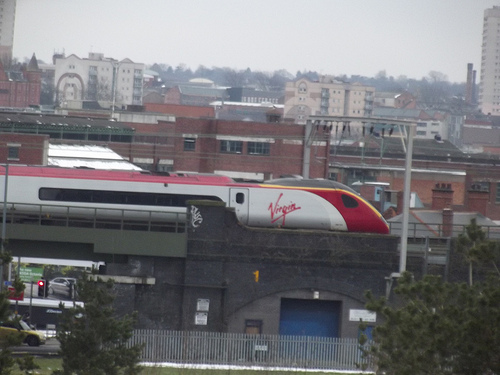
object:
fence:
[120, 326, 390, 373]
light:
[37, 280, 44, 287]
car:
[46, 277, 93, 298]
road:
[22, 282, 38, 292]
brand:
[267, 193, 302, 227]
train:
[1, 164, 393, 233]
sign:
[196, 298, 210, 311]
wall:
[265, 228, 398, 287]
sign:
[348, 308, 376, 322]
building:
[478, 9, 500, 119]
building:
[101, 197, 498, 373]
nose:
[375, 207, 390, 234]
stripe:
[258, 182, 353, 192]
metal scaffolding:
[301, 107, 417, 268]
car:
[1, 314, 47, 348]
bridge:
[0, 199, 499, 340]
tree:
[58, 275, 145, 373]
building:
[51, 52, 144, 106]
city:
[0, 0, 500, 372]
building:
[279, 77, 380, 123]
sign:
[19, 268, 46, 282]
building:
[0, 107, 332, 187]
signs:
[193, 311, 208, 326]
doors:
[275, 294, 343, 368]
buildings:
[3, 131, 49, 165]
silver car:
[45, 277, 77, 297]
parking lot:
[5, 273, 79, 300]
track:
[2, 207, 497, 251]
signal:
[38, 280, 46, 288]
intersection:
[5, 266, 76, 355]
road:
[22, 345, 61, 353]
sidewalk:
[144, 356, 359, 372]